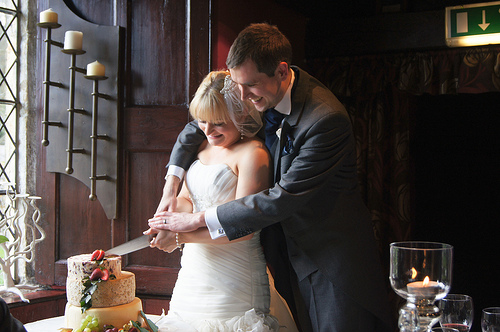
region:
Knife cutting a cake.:
[51, 222, 168, 329]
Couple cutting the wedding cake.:
[47, 11, 396, 329]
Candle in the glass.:
[372, 236, 459, 304]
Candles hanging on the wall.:
[21, 5, 121, 200]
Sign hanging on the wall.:
[428, 4, 498, 51]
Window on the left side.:
[3, 28, 38, 248]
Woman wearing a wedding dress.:
[148, 63, 293, 324]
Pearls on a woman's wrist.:
[173, 231, 183, 249]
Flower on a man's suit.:
[272, 125, 305, 160]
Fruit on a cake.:
[88, 245, 111, 289]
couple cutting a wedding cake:
[50, 19, 394, 330]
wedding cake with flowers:
[60, 248, 152, 330]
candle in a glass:
[381, 230, 453, 303]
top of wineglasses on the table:
[434, 289, 498, 329]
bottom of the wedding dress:
[182, 254, 262, 327]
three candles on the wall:
[35, 3, 117, 205]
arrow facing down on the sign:
[475, 6, 490, 36]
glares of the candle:
[394, 258, 419, 280]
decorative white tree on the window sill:
[5, 184, 48, 309]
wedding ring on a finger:
[160, 219, 170, 225]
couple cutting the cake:
[73, 15, 357, 330]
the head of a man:
[211, 5, 339, 125]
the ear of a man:
[270, 45, 297, 93]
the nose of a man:
[235, 78, 262, 108]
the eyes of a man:
[224, 68, 278, 100]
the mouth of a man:
[243, 81, 268, 123]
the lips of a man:
[245, 82, 291, 122]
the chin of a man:
[246, 94, 287, 135]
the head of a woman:
[171, 64, 272, 180]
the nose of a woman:
[186, 109, 243, 148]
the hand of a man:
[145, 191, 213, 278]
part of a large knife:
[95, 234, 154, 254]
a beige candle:
[87, 61, 102, 73]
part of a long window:
[1, 3, 28, 280]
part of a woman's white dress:
[160, 160, 269, 330]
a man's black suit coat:
[165, 65, 382, 330]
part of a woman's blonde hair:
[187, 67, 242, 129]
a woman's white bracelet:
[170, 228, 185, 250]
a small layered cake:
[63, 247, 140, 329]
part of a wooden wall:
[118, 0, 186, 105]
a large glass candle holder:
[389, 241, 454, 308]